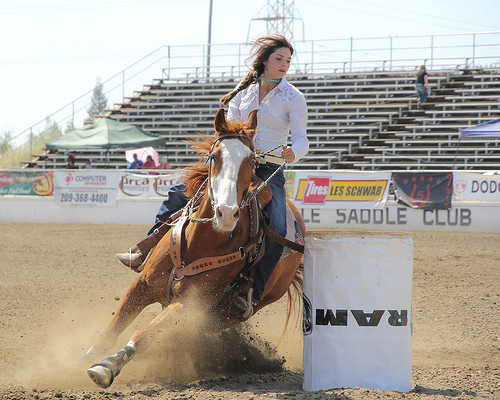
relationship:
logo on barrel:
[300, 296, 409, 336] [300, 231, 418, 397]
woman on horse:
[117, 31, 312, 306] [72, 107, 307, 392]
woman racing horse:
[117, 31, 312, 306] [72, 107, 307, 392]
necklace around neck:
[255, 76, 281, 83] [258, 70, 284, 90]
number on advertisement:
[59, 189, 109, 203] [52, 167, 119, 206]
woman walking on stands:
[414, 65, 429, 110] [309, 63, 499, 163]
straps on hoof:
[90, 347, 134, 387] [77, 355, 120, 381]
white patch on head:
[217, 141, 247, 216] [198, 102, 268, 242]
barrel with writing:
[300, 239, 411, 397] [311, 302, 408, 333]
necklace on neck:
[255, 76, 280, 83] [256, 76, 281, 89]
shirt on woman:
[233, 79, 305, 151] [202, 7, 324, 177]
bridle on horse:
[164, 210, 264, 293] [72, 107, 307, 392]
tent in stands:
[44, 113, 172, 170] [0, 28, 499, 172]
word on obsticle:
[316, 292, 412, 332] [285, 216, 437, 397]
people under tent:
[60, 151, 158, 171] [50, 117, 167, 179]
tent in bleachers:
[458, 115, 498, 145] [24, 68, 499, 173]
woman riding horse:
[117, 31, 312, 306] [72, 107, 307, 392]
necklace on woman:
[255, 76, 281, 83] [117, 31, 312, 306]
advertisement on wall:
[293, 174, 390, 208] [1, 169, 498, 233]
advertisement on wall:
[389, 172, 451, 207] [1, 169, 498, 233]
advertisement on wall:
[452, 169, 498, 199] [1, 169, 498, 233]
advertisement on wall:
[116, 171, 187, 198] [1, 169, 498, 233]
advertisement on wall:
[52, 167, 119, 206] [1, 169, 498, 233]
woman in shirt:
[402, 65, 441, 111] [414, 69, 430, 88]